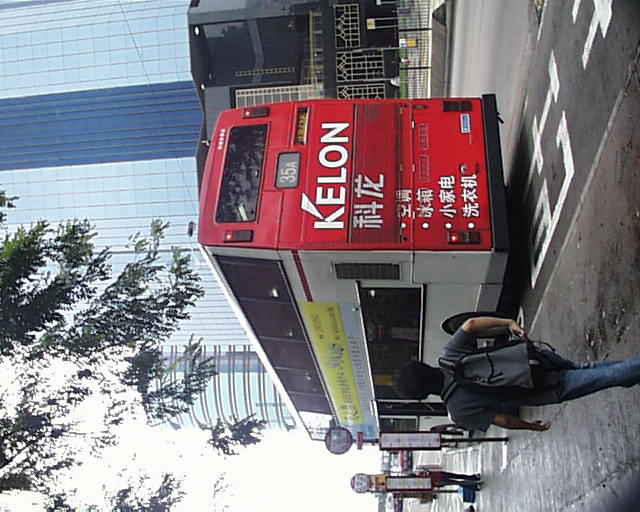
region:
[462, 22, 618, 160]
Road is grey color.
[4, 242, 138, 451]
Leaves are green color.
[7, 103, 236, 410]
Buildings are blue color.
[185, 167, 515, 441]
Bus is white and red color.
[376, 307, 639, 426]
man is walking in sidewalk.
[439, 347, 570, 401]
Bagpack is black and grey color.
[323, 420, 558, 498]
Sign boards are in sidewalk.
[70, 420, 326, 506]
Sky is white color.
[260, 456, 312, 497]
a view of sky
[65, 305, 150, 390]
a view of trees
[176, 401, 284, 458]
a view of leafs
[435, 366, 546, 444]
a view of man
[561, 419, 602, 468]
a view of road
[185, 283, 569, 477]
a view of bus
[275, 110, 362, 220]
text on the bus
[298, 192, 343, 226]
the letter is white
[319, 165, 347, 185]
the letter is white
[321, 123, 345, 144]
the letter is white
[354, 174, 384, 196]
the letter is white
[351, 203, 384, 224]
the letter is white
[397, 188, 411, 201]
the letter is white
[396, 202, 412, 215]
the letter is white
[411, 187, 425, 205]
the letter is white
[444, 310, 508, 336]
tire belongs to bus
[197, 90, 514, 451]
bus travels down street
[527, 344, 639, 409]
pants worn by human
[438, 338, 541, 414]
backpack worn by human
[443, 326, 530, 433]
shirt worn by human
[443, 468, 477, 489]
pants worn by human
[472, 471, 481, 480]
shoe worn by human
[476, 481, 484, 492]
shoe worn by human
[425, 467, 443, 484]
shirt worn by human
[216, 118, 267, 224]
rear window belongs to bus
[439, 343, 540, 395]
man wearing a back pack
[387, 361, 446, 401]
man has black hair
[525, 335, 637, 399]
man wearing blue jeans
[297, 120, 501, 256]
writing on the bus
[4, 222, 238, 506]
leaves on the trees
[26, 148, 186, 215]
windows on the building